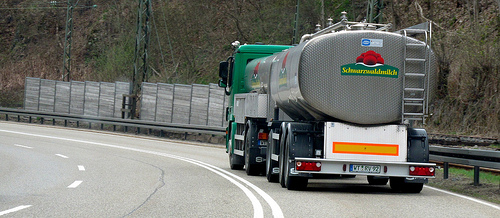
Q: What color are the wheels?
A: Black.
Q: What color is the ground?
A: Grey.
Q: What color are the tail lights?
A: Red.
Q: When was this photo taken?
A: Daytime.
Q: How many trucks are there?
A: One.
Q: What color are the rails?
A: Silver.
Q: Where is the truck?
A: On the road.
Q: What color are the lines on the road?
A: White.